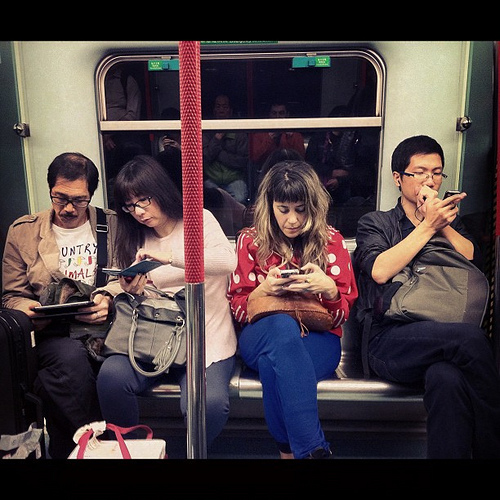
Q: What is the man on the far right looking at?
A: Cell phone.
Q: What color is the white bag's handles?
A: Red.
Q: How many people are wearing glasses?
A: Three.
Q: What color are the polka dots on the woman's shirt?
A: White.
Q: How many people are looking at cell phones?
A: Two.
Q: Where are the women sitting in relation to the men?
A: Between the men.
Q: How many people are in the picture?
A: Four.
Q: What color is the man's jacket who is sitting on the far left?
A: Brown.